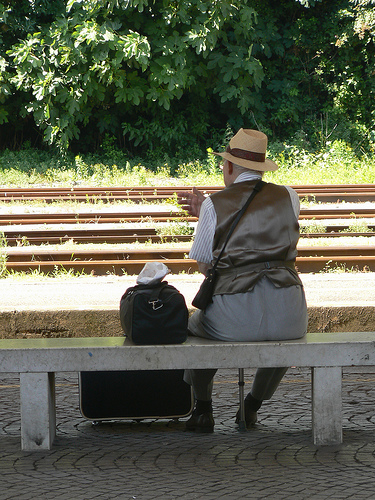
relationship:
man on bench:
[180, 127, 307, 429] [1, 329, 372, 448]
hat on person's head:
[219, 120, 281, 169] [216, 131, 275, 186]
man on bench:
[176, 127, 307, 433] [11, 318, 364, 447]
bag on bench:
[120, 281, 189, 344] [5, 295, 363, 451]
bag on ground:
[78, 370, 194, 422] [0, 364, 362, 498]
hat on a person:
[211, 127, 278, 171] [184, 127, 307, 434]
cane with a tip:
[220, 357, 287, 436] [237, 421, 249, 432]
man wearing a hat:
[176, 127, 307, 433] [213, 127, 274, 169]